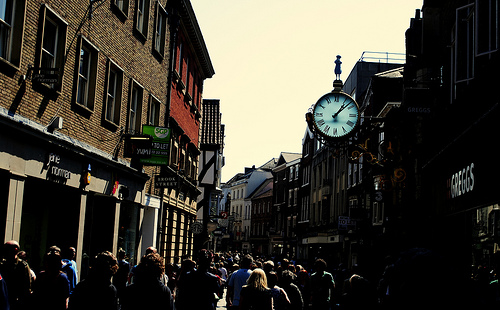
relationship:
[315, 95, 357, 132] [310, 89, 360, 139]
face of clock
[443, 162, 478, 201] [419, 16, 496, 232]
sign on front of building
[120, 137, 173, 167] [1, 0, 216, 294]
sign on front of building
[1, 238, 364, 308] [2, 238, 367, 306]
crowd of people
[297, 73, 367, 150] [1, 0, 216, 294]
window on building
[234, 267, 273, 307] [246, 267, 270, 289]
person has hair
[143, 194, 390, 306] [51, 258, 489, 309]
people in street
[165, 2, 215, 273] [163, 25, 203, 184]
building has wall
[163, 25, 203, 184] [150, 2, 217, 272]
wall supporting building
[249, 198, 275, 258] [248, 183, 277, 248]
facade adorning building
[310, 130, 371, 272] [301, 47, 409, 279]
facade adorning building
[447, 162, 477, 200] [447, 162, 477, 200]
sign reading sign